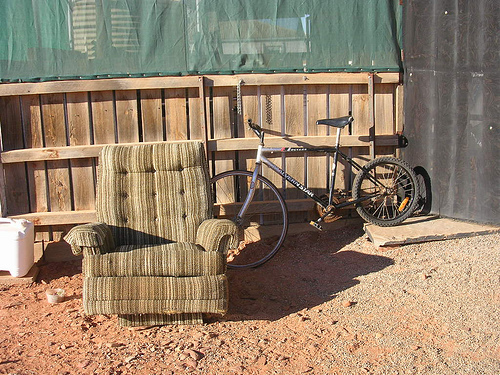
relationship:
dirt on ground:
[316, 291, 456, 361] [342, 262, 445, 322]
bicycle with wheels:
[211, 118, 429, 260] [221, 169, 418, 246]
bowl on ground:
[43, 284, 71, 304] [342, 262, 445, 322]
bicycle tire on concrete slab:
[352, 165, 423, 224] [361, 225, 490, 245]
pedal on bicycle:
[306, 216, 340, 240] [211, 118, 429, 260]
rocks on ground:
[129, 338, 224, 371] [342, 262, 445, 322]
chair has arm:
[64, 145, 236, 323] [193, 221, 244, 250]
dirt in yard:
[316, 291, 456, 361] [3, 5, 489, 373]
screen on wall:
[3, 2, 398, 67] [4, 86, 403, 193]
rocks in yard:
[129, 338, 224, 371] [3, 5, 489, 373]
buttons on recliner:
[175, 166, 193, 222] [64, 145, 236, 323]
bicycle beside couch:
[211, 118, 429, 260] [64, 145, 236, 323]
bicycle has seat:
[211, 118, 429, 260] [312, 112, 359, 128]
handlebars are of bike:
[238, 115, 269, 134] [211, 118, 429, 260]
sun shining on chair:
[95, 150, 231, 240] [64, 145, 236, 323]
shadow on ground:
[212, 230, 395, 323] [342, 262, 445, 322]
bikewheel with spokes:
[352, 165, 423, 224] [217, 182, 285, 221]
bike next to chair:
[211, 118, 429, 260] [64, 145, 236, 323]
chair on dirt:
[64, 145, 236, 323] [316, 291, 456, 361]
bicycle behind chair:
[211, 118, 429, 260] [64, 145, 236, 323]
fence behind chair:
[92, 75, 356, 133] [64, 145, 236, 323]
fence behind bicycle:
[92, 75, 356, 133] [211, 118, 429, 260]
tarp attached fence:
[3, 2, 398, 67] [92, 75, 356, 133]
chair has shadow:
[64, 145, 236, 323] [212, 230, 395, 323]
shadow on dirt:
[212, 230, 395, 323] [316, 291, 456, 361]